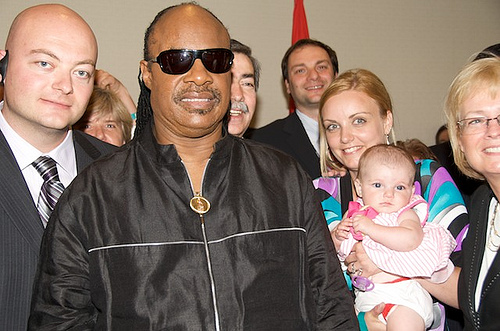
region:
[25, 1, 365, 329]
the great singer Stevie Wonder poses with some other people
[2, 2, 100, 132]
this man posing with Stevie Wonder is bald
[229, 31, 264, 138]
this man posing with Stevie Wonder wears a mustache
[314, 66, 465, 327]
this woman posing with Stevie Wonder is holding a baby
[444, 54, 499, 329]
this woman posing with Stevie Wonder wears glasses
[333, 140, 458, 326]
this baby posed with Stevie Wonder is wearing a striped dress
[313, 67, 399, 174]
this lady posing with Stevie Wonder is wearing dangly earrings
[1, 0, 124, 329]
this man posing with Stevie Wonder is wearing a suit and tie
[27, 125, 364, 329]
Stevie Wonder is wearing a black top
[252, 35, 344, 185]
this man posing with Stevie Wonder looks pretty happy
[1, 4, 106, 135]
the head of a man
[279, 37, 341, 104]
the head of a man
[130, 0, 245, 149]
the head of Stevie Wonder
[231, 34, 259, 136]
the head of a man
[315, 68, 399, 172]
the head of a woman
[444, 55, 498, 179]
the head of a woman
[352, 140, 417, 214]
the head of a baby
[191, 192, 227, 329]
a zipper of a jacket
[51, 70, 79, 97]
the nose of a man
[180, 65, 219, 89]
the nose of a man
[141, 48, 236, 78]
Sunglasses being worn by a guy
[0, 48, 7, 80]
An earpiece on an ear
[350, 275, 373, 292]
A purple plastic pacifier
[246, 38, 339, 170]
Man wearing a suit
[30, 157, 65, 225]
Black and gray tie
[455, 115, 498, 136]
Eye glasses on a lady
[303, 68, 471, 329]
A woman holding a baby in her arms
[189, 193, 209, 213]
A gold zipper on a sweatsuit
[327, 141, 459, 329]
baby in someones's arm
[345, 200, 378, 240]
A pink cloth in a baby's possession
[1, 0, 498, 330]
a photo of mr. wonder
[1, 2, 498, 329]
a group photo where people are posing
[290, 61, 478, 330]
a baby in woman's arms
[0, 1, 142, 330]
a bald man in a suit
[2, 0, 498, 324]
a scene inside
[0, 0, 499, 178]
a white wall in background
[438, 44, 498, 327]
a woman wearing glasses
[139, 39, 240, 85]
pair of black sunglasses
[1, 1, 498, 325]
a bunch of people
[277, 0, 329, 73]
a red object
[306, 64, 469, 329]
A woman holding a baby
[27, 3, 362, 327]
The man is musician Stevie Wonder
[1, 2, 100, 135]
A man has no hair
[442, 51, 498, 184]
A woman with blonde hair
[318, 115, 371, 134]
A pair of blue eyes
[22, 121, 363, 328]
The jacket is black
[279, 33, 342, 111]
A man has brown hair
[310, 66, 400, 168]
The woman is smiling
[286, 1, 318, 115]
A red flag behind a man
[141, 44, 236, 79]
A pair of black sunglasses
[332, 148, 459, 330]
baby in pink and white shirt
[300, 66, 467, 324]
woman holding baby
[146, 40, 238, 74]
black plastic sunglasses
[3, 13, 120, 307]
man with bald head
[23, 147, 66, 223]
gray and black striped tie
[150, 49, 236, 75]
the man is wearing sunglasses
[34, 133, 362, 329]
the man is wearing a jacket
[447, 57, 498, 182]
the woman has blond hair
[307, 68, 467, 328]
the woman is holding a baby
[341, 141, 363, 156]
the woman is smiling